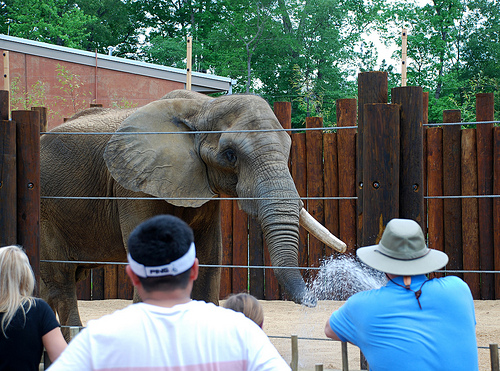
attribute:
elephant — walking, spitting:
[41, 91, 308, 303]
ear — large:
[102, 98, 219, 209]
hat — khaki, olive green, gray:
[355, 217, 448, 277]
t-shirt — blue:
[327, 272, 481, 369]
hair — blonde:
[1, 242, 35, 340]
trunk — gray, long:
[235, 174, 312, 300]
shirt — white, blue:
[43, 297, 293, 369]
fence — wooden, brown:
[5, 69, 497, 301]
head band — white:
[127, 241, 196, 278]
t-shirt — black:
[1, 297, 62, 369]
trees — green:
[0, 1, 498, 126]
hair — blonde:
[222, 290, 262, 327]